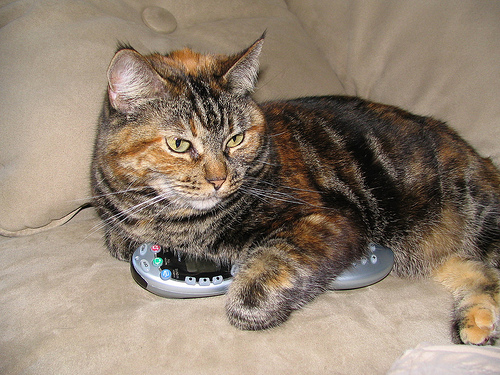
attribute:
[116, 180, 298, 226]
whiskers — are white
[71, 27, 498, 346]
cat — is calico, is brown, is black, is gold calico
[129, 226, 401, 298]
remote control — is black, is grey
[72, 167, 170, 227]
whiskers — are white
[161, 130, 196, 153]
eye — is green, is green-gold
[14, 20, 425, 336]
couch — is creamy beige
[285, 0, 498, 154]
cushion — is tan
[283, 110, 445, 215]
cat — is black, is grey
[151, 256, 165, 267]
button — is green, is round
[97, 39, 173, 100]
ear — is pointed, is tufted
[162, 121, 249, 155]
eyes — are yellow